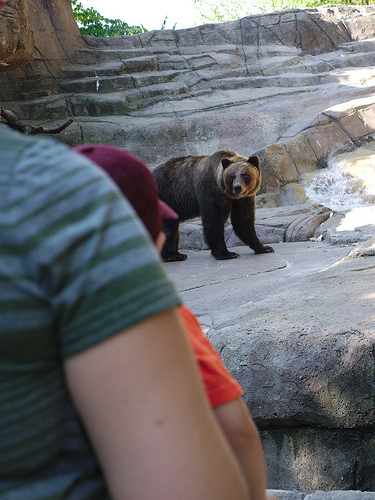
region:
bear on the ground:
[173, 130, 284, 238]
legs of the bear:
[207, 213, 275, 261]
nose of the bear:
[231, 183, 246, 195]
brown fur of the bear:
[165, 164, 222, 197]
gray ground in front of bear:
[268, 249, 302, 279]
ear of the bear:
[246, 148, 266, 171]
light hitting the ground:
[340, 196, 370, 222]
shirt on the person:
[14, 181, 129, 296]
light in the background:
[112, 4, 188, 37]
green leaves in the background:
[92, 15, 140, 36]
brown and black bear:
[152, 148, 273, 259]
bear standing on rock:
[154, 150, 274, 261]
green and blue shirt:
[0, 124, 182, 498]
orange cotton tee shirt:
[179, 304, 246, 410]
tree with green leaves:
[70, 1, 176, 37]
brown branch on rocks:
[0, 107, 74, 135]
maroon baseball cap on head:
[75, 142, 177, 223]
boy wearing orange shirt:
[70, 143, 269, 499]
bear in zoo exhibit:
[151, 149, 273, 261]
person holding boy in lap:
[0, 123, 253, 498]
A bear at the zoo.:
[150, 147, 275, 262]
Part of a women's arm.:
[61, 305, 248, 499]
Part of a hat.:
[71, 143, 180, 241]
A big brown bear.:
[152, 148, 275, 262]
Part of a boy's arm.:
[212, 397, 267, 498]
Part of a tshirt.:
[0, 233, 181, 497]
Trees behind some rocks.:
[72, 0, 374, 36]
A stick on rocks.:
[2, 107, 74, 135]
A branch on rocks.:
[1, 108, 73, 133]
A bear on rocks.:
[152, 147, 276, 262]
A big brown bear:
[148, 142, 281, 263]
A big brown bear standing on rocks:
[139, 108, 281, 284]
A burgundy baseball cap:
[77, 140, 173, 231]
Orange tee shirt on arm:
[184, 306, 249, 412]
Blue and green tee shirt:
[20, 141, 156, 334]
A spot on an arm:
[133, 393, 180, 442]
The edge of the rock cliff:
[238, 323, 374, 448]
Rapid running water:
[307, 159, 366, 238]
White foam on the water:
[316, 173, 357, 207]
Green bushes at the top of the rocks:
[75, 7, 140, 38]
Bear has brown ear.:
[244, 148, 271, 175]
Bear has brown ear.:
[212, 140, 225, 180]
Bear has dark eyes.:
[223, 171, 251, 180]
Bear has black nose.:
[230, 181, 250, 196]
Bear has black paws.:
[199, 223, 295, 268]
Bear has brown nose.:
[225, 158, 255, 179]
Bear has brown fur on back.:
[160, 147, 205, 167]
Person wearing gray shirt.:
[37, 272, 100, 305]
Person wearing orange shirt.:
[190, 322, 235, 395]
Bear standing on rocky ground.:
[167, 230, 296, 288]